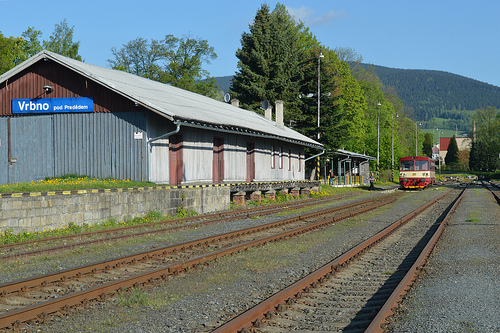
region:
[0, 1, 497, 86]
blue of daytime sky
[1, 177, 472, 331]
three sets of train tracks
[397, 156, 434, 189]
front of red and white train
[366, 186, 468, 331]
metal rail of train track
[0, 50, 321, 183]
building with slanted roof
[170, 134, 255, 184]
three doors of building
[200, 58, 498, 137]
hills of trees on horizon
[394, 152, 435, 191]
train on a set of tracks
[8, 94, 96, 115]
blue sign on a barn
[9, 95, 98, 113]
blue sign with white writing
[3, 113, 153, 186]
grey siding on a big barn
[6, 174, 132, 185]
yellow flowers near a big barn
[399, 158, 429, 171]
window on the front of a train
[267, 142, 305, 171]
four windows on a barn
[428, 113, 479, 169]
building in the background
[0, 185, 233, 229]
stone wall on the side of the tracks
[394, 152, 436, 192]
a red and white train car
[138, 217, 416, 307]
three sets of train tracks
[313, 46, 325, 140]
a tall security light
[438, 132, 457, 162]
a building with a red roof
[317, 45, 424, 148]
several trees in a row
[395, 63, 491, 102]
a hillside covered with trees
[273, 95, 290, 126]
a chimney on a roof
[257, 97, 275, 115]
a satellite dish on a roof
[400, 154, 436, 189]
The trolley on the track.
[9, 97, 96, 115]
The blue sign on the building.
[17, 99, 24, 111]
The letter V on the blue sign.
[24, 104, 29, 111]
The letter r on the blue sign.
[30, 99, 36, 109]
The letter b on the blue sign.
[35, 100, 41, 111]
The letter n on the blue sign.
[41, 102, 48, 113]
The letter o on the blue sign.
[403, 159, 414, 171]
The left window of the trolley.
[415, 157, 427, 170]
The right window of the trolley.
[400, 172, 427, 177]
The headlights of the trolley.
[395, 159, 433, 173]
front windshield on a train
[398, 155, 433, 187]
red and white train on a track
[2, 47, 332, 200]
large barn with aluminum siding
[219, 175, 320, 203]
porch near the barn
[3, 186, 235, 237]
short stone wall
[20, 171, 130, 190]
yellow flowers near the barn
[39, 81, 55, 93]
light above a blue sign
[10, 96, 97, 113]
blue and white sign on a barn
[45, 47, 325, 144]
roof on a barn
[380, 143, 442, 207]
the train is red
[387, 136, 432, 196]
the train is red